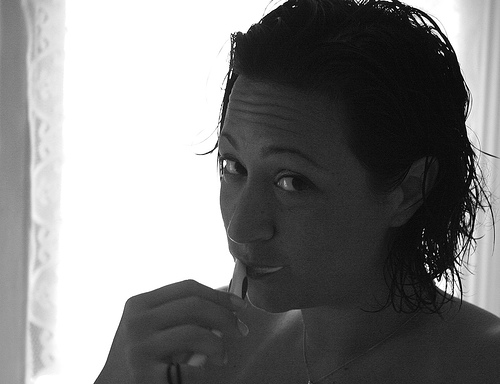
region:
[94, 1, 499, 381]
a woman brushing her teeth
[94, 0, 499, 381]
a woman holding a toothbrush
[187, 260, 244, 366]
a white plastic toothbrush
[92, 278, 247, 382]
a woman's right hand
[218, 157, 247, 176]
a woman's right eye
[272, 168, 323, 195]
a woman's left eye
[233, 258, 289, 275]
a woman's tiny mouth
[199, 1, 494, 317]
a woman's wet hair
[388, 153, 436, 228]
a woman's left ear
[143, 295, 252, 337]
a woman's middle finger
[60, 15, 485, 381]
A woman brushing her teeth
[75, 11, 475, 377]
A woman brushing her teeth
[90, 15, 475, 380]
A woman brushing her teeth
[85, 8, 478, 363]
A woman brushing her teeth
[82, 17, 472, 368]
A woman brushing her teeth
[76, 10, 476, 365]
A woman brushing her teeth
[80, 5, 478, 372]
A woman brushing her teeth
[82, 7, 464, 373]
A woman brushing her teeth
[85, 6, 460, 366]
A woman brushing her teeth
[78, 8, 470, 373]
A woman brushing her teeth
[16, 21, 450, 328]
this is in a bathroom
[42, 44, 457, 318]
this photo is in grayscale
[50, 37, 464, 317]
this photo is in black and white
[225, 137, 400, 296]
the woman is looking at the camera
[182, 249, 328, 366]
the lady is holding a toothbrush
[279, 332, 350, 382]
the womans has on a necklace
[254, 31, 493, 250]
the woman's hair is wet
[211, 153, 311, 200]
eyes of the woman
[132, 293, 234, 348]
fingers on the hand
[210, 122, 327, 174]
eyebrows of the woman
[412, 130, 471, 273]
woman's hair is wet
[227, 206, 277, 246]
nose of the woman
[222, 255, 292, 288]
mouth of the woman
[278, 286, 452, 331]
neck of the woman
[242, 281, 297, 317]
chin of the woman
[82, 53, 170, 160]
the background is bright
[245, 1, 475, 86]
black hair on woman's hair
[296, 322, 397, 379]
chain on the woman's neck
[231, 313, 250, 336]
nail on the woman's finger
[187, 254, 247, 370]
toothbrush in woman's hand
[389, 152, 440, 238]
left ear on the woman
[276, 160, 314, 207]
the woman's left eye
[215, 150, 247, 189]
the woman's right eye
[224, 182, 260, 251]
the nose on woman's face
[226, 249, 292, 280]
the woman's lips on her face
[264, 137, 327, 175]
the woman's left eyebrow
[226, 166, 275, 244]
Nose on a woman.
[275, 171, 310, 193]
A woman's left eye.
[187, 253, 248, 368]
White and grey toothbrush in a woman's mouth.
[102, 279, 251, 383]
A woman's right hand.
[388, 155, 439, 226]
Woman's left ear.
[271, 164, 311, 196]
left eye of a woman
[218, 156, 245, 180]
right eye of a woman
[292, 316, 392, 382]
necklace on a woman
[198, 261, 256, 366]
a black and white toothbrush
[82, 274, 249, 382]
hand of a woman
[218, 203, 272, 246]
nose of a woman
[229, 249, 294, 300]
mouth of a woman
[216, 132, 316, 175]
eyebrows of a woman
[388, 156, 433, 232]
ear of a woman